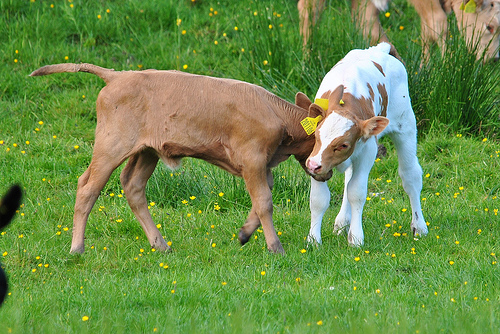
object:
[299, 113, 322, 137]
tag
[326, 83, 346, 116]
calves ear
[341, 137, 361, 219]
legs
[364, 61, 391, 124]
spots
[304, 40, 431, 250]
calf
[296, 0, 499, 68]
calf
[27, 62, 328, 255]
brown cow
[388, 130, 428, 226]
leg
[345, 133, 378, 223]
leg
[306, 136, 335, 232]
leg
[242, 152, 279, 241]
leg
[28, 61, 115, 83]
tail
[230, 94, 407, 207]
cow eating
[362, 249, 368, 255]
flower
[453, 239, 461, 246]
flower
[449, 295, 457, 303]
flower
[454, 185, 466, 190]
flower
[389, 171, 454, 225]
ground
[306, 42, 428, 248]
brown and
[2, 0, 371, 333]
grass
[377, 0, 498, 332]
grass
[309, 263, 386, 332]
grass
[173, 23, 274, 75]
grass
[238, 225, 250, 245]
hoof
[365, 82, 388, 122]
markings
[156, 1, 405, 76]
flowers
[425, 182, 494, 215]
flowers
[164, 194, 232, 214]
flowers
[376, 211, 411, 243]
flowers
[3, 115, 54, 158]
flowers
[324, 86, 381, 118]
markings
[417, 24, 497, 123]
grass blades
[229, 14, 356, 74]
grass blades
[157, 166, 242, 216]
grass blades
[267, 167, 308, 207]
grass blades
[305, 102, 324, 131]
ear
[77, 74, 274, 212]
body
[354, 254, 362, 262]
dandelions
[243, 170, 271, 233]
legs